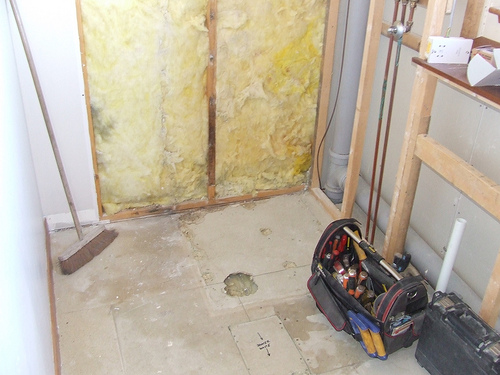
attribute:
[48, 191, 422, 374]
floor — cracked, old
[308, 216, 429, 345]
box — plastic, open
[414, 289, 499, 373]
case — plastic, black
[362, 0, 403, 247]
tube — copper, plumbing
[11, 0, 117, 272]
broom — wooden, handle, push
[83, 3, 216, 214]
insulation — exposed, yellow, old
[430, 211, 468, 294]
pipe — pvc